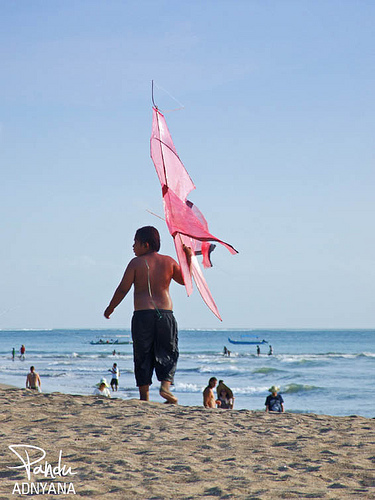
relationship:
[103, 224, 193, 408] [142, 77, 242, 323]
boy holding up a kite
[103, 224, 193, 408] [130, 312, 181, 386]
boy wearing pants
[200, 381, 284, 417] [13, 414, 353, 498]
people walking on beach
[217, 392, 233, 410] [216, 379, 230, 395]
woman wearing a hat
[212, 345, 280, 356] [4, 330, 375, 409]
people are swimming in ocean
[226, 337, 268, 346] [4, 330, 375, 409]
boat on top of ocean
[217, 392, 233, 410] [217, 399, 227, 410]
woman wearing a shirt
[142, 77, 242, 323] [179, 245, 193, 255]
kite held in right hand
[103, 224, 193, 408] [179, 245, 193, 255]
boy has a right hand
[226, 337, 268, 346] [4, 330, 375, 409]
boat on traveling on ocean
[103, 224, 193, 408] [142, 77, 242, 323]
boy holding kite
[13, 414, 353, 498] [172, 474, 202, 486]
beach full of sand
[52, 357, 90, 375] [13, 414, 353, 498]
waves are heading toward beach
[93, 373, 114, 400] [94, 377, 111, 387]
person wears brimmed hat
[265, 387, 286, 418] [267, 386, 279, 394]
person wearing brimmed hat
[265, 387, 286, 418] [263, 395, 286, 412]
person wearing shirt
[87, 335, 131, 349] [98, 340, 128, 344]
boat carrying many people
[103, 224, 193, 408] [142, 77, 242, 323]
boy carrying a kite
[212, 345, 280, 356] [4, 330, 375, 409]
people are playing in ocean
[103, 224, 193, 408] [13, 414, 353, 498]
boy walking on beach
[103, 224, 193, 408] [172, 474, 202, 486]
boy walking on sand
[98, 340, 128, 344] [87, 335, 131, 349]
people are sitting in a boat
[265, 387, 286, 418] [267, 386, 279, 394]
person wearing a brimmed hat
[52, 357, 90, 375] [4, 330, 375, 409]
waves are on top of ocean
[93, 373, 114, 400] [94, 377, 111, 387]
person wearing a brimmed hat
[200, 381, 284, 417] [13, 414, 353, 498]
people are playing on beach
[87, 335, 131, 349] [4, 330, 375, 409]
boat on top of ocean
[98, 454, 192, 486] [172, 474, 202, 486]
footprints are imprinted on top sand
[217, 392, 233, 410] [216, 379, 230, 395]
woman wearing hat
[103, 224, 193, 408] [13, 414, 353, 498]
boy standing on beach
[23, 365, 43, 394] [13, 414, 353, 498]
man standing on beach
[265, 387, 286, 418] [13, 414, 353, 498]
man behind beach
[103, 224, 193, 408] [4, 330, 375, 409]
boy walking toward ocean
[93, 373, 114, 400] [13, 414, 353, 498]
person behind beach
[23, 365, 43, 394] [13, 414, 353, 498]
man behind beach